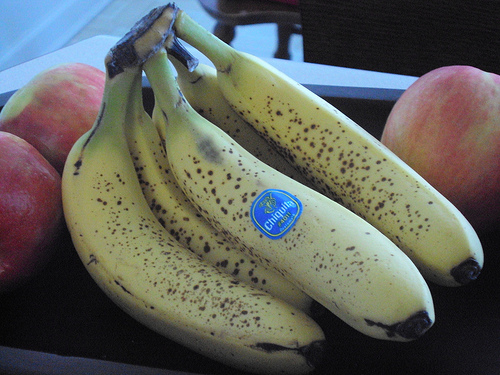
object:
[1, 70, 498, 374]
surface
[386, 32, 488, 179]
apple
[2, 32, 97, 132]
apple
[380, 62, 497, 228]
orange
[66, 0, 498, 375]
banana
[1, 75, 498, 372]
tray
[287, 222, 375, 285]
banana peel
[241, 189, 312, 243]
label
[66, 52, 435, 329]
fruit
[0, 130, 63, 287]
apple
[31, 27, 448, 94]
counter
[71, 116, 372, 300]
spots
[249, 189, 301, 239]
sticker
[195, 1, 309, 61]
chair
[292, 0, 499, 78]
table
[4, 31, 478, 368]
bin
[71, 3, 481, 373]
bunch